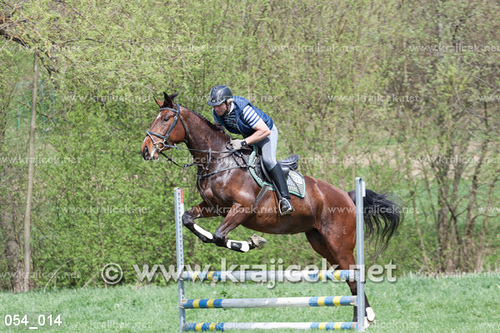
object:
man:
[205, 86, 292, 215]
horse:
[137, 86, 407, 327]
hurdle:
[172, 290, 372, 332]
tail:
[345, 179, 410, 260]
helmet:
[203, 83, 236, 107]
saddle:
[277, 148, 305, 182]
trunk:
[19, 46, 44, 293]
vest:
[210, 93, 277, 140]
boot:
[262, 160, 297, 219]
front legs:
[192, 227, 273, 259]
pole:
[352, 172, 370, 332]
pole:
[173, 271, 364, 283]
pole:
[182, 293, 359, 311]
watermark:
[94, 257, 401, 288]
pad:
[244, 147, 313, 200]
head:
[137, 91, 184, 159]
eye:
[160, 114, 170, 123]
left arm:
[228, 102, 271, 152]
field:
[0, 267, 500, 333]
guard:
[178, 215, 212, 246]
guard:
[223, 231, 252, 256]